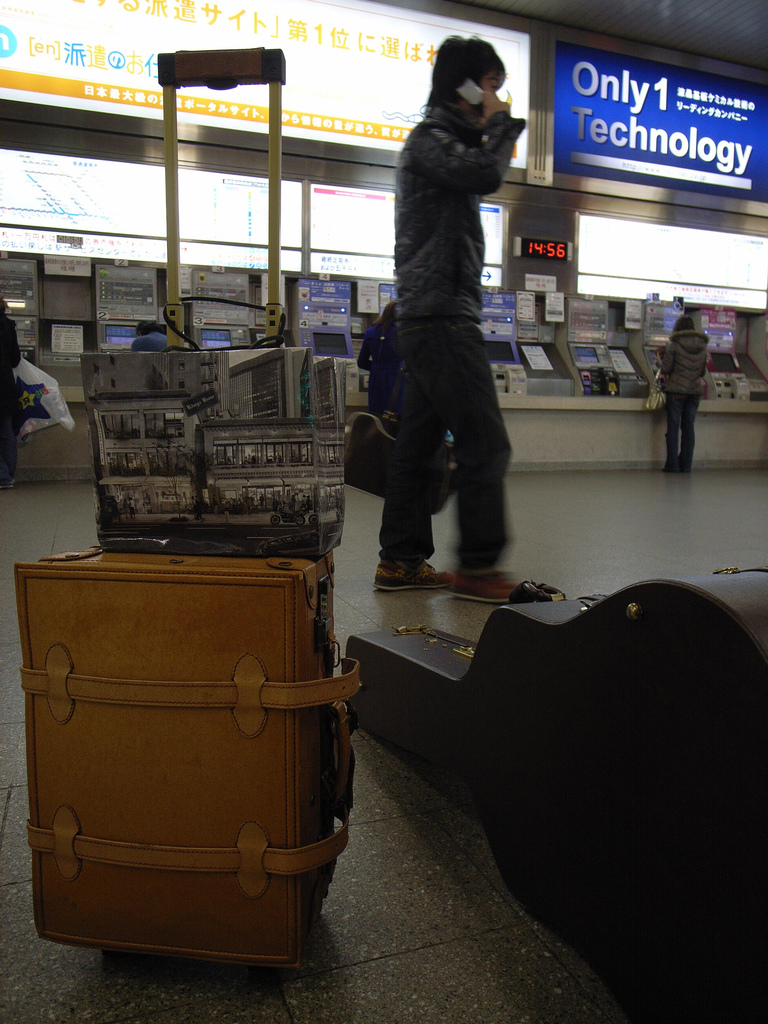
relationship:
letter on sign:
[623, 76, 656, 119] [545, 51, 765, 204]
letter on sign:
[568, 101, 595, 146] [545, 51, 765, 204]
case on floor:
[346, 557, 764, 1022] [0, 473, 764, 1024]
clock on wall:
[506, 231, 577, 260] [0, 0, 768, 471]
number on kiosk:
[298, 318, 309, 327] [294, 276, 365, 372]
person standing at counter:
[659, 307, 713, 477] [369, 395, 765, 474]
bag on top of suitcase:
[78, 293, 348, 554] [6, 50, 363, 971]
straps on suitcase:
[269, 645, 356, 875] [6, 50, 363, 971]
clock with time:
[511, 232, 575, 264] [520, 238, 570, 257]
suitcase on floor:
[20, 537, 346, 958] [14, 797, 379, 1020]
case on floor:
[346, 576, 764, 1020] [360, 618, 706, 1020]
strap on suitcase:
[260, 649, 366, 716] [20, 537, 346, 958]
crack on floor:
[372, 934, 483, 961] [346, 883, 516, 991]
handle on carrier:
[162, 51, 282, 338] [101, 43, 343, 565]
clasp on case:
[391, 615, 421, 642] [352, 604, 516, 726]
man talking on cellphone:
[399, 32, 547, 587] [455, 76, 488, 112]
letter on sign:
[567, 54, 597, 107] [556, 46, 737, 171]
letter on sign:
[595, 74, 617, 107] [559, 51, 709, 171]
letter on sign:
[617, 65, 636, 106] [573, 40, 690, 162]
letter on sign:
[623, 82, 656, 118] [567, 51, 675, 154]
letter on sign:
[567, 96, 600, 149] [567, 65, 647, 165]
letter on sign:
[612, 110, 628, 151] [567, 57, 653, 174]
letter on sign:
[645, 115, 667, 159] [564, 62, 723, 210]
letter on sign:
[665, 129, 695, 165] [601, 62, 726, 170]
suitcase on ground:
[20, 537, 346, 958] [17, 847, 394, 995]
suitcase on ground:
[0, 517, 366, 992] [318, 660, 468, 900]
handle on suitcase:
[232, 830, 276, 908] [39, 548, 335, 969]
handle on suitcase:
[48, 808, 78, 883] [20, 537, 346, 958]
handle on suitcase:
[95, 529, 173, 562] [20, 537, 346, 958]